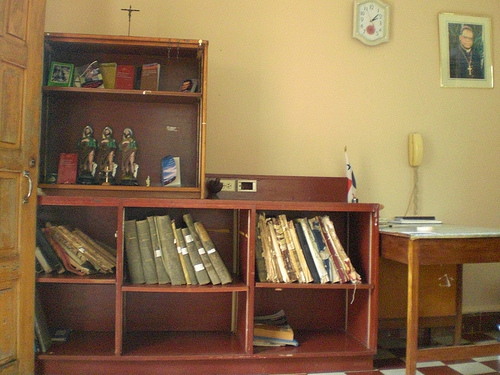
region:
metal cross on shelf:
[112, 4, 154, 34]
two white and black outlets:
[206, 157, 269, 207]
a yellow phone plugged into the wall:
[386, 110, 435, 218]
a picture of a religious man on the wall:
[438, 7, 491, 103]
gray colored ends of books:
[127, 211, 251, 288]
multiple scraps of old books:
[268, 219, 366, 278]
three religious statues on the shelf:
[71, 125, 171, 195]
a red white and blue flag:
[325, 144, 372, 207]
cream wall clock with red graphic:
[347, 1, 411, 63]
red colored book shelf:
[62, 192, 370, 361]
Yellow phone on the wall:
[402, 125, 441, 177]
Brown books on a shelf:
[123, 215, 237, 292]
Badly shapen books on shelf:
[254, 210, 372, 289]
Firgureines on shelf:
[73, 118, 150, 186]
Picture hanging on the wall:
[430, 7, 498, 96]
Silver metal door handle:
[12, 155, 34, 206]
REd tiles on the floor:
[415, 360, 458, 373]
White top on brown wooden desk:
[387, 224, 488, 244]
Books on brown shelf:
[41, 53, 163, 95]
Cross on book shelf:
[112, 3, 154, 31]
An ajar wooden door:
[4, 0, 46, 370]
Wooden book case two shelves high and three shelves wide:
[31, 196, 387, 373]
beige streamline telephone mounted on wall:
[406, 130, 426, 169]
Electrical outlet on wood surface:
[218, 178, 236, 193]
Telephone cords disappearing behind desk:
[402, 167, 426, 214]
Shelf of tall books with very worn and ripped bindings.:
[256, 210, 365, 282]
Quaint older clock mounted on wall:
[350, 0, 391, 46]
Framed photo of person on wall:
[435, 8, 495, 89]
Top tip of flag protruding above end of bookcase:
[341, 142, 363, 202]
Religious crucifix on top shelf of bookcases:
[118, 4, 144, 34]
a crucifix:
[118, 0, 148, 42]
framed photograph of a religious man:
[431, 7, 498, 91]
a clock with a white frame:
[353, 1, 398, 52]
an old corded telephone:
[400, 123, 446, 205]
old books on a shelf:
[41, 201, 366, 292]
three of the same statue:
[78, 118, 149, 186]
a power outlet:
[218, 176, 240, 191]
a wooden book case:
[48, 28, 385, 373]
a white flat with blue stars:
[338, 140, 370, 216]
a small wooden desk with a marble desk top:
[392, 223, 487, 371]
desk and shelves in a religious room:
[0, 5, 485, 360]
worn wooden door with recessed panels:
[0, 0, 45, 370]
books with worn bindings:
[250, 210, 360, 280]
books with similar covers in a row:
[120, 205, 245, 290]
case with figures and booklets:
[40, 30, 205, 195]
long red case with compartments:
[35, 175, 380, 370]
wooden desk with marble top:
[380, 200, 495, 370]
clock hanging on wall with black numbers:
[350, 0, 390, 45]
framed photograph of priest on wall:
[435, 5, 490, 85]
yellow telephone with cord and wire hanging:
[395, 126, 425, 211]